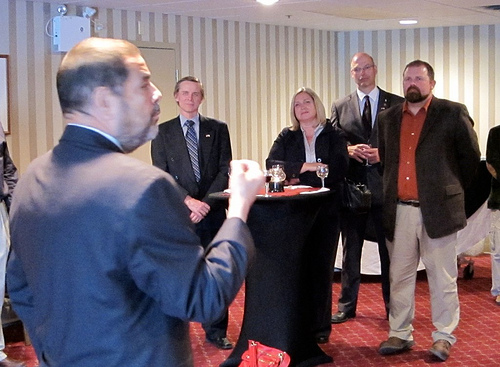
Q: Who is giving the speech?
A: Man in gray suit.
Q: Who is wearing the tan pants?
A: Man in orange shirt.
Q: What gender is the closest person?
A: Male.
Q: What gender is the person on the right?
A: Male.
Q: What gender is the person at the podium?
A: Female.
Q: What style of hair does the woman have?
A: Shoulder length and blonde.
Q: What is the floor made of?
A: Tile.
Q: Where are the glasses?
A: On the podium.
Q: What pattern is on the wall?
A: Stripes.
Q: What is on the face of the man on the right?
A: Beard.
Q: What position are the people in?
A: Standing.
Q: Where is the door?
A: Behind the man on the left in the back.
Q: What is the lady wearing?
A: Jacket.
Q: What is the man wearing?
A: Pant.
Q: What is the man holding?
A: Wine glass.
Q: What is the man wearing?
A: Coat.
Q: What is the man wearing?
A: Coat.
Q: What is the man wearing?
A: Coat.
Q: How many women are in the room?
A: One.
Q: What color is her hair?
A: Blonde.